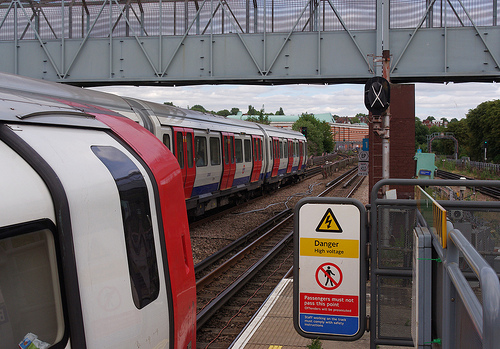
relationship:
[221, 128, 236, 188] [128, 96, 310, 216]
door on train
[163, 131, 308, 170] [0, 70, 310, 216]
window on train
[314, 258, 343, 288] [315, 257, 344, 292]
emblem has cirlce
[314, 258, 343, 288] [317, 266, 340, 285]
emblem has line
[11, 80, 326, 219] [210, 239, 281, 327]
train on track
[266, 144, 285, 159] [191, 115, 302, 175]
window on train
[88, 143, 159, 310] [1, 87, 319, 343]
window on train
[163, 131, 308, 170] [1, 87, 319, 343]
window on train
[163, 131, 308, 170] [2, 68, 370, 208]
window on train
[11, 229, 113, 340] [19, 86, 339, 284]
window on train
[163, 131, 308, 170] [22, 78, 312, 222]
window on train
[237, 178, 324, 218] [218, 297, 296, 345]
cords on ground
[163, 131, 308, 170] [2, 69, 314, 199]
window on train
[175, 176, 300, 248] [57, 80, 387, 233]
wheels are on train